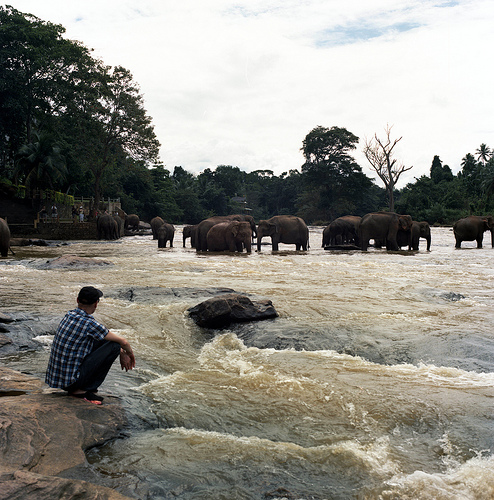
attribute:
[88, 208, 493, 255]
elephants — drinking, huddled together, together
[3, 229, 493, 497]
water — river, brown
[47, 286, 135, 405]
man — squatting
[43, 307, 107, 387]
shirt — blue plaid, blue, plaid, white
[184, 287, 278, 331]
rock — boulder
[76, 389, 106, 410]
shoes — black, orange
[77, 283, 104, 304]
cap — black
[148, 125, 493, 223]
trees — green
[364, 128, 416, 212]
tree — bare, bare]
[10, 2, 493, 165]
sky — white, cloudy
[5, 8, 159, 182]
leaves — green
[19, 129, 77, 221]
tree — coconut tree